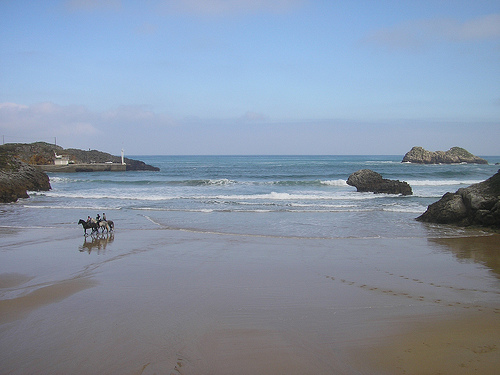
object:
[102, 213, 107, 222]
person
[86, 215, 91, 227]
horseback riders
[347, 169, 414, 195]
rock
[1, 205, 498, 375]
shore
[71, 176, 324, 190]
waves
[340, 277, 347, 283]
tracks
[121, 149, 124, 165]
pole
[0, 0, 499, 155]
sky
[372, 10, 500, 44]
clouds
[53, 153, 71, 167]
beach house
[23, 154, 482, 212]
ocean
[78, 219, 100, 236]
black horse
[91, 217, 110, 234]
horses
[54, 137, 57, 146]
tower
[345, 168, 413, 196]
boulder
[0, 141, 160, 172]
mountain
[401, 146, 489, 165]
rock island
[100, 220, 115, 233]
horses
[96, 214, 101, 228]
person